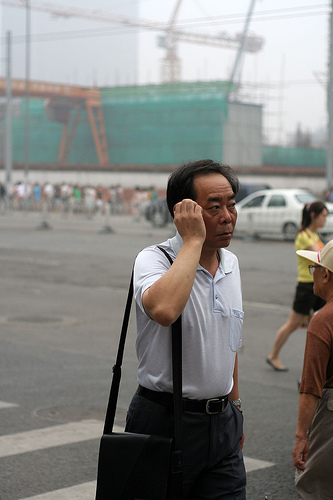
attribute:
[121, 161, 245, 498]
man — walking, carrying, asian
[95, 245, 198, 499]
satchel — black, worn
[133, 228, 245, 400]
shirt — white, blue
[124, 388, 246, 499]
pants — gray, black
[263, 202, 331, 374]
woman — strolling, walking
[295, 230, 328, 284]
shirt — yellow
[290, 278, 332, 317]
skirt — black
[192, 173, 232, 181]
hairline — receding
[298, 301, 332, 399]
shirt — brown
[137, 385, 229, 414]
belt — black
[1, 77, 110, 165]
structure — orange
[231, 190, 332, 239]
car — parked, white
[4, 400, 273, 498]
lines — white, painted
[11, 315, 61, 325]
cover — manhole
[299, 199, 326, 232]
hair — brown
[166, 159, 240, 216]
hair — dark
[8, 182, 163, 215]
people — walking, lined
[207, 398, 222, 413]
buckle — silver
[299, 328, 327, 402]
sleeve — brown